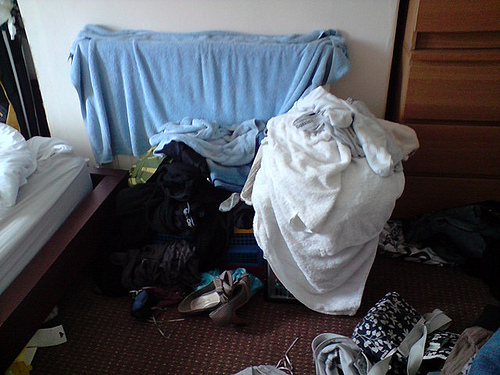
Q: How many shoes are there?
A: One.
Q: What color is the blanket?
A: White.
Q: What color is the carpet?
A: Purple.